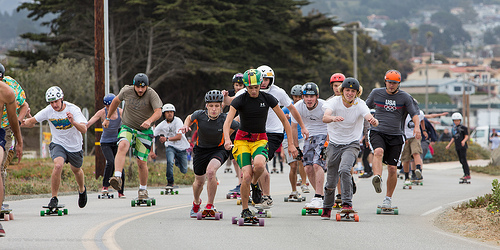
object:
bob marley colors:
[236, 129, 251, 140]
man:
[316, 76, 381, 220]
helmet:
[383, 69, 402, 84]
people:
[222, 69, 299, 222]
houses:
[393, 79, 478, 96]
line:
[100, 206, 193, 250]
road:
[0, 159, 497, 250]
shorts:
[114, 125, 153, 162]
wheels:
[214, 212, 221, 220]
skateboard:
[230, 215, 264, 226]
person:
[101, 70, 165, 201]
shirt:
[319, 96, 372, 145]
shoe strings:
[193, 213, 199, 214]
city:
[359, 0, 500, 57]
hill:
[334, 0, 499, 58]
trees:
[0, 0, 414, 119]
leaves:
[226, 35, 233, 40]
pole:
[91, 0, 111, 179]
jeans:
[98, 141, 125, 194]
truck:
[465, 124, 500, 148]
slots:
[141, 80, 144, 82]